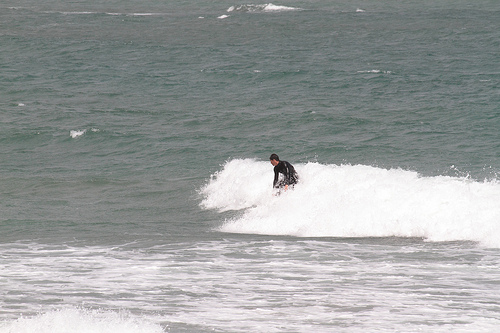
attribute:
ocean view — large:
[9, 7, 496, 326]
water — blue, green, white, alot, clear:
[3, 3, 498, 327]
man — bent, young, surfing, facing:
[264, 149, 301, 201]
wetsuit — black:
[274, 157, 298, 188]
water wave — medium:
[193, 153, 499, 241]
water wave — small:
[3, 304, 165, 330]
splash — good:
[5, 256, 500, 328]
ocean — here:
[7, 6, 499, 322]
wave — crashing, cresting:
[198, 148, 500, 254]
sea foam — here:
[3, 151, 498, 326]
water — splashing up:
[2, 297, 177, 327]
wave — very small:
[1, 301, 171, 331]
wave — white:
[209, 0, 296, 19]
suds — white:
[7, 152, 499, 319]